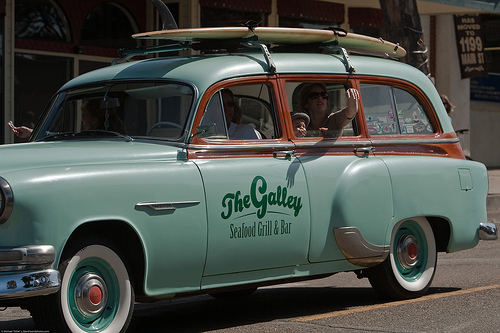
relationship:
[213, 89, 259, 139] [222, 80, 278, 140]
man looking out window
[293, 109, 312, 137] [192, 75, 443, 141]
child looking out back window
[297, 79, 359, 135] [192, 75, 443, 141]
woman looking out back window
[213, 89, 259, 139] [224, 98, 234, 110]
man wearing sunglasses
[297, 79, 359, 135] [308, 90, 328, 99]
woman wearing sunglasses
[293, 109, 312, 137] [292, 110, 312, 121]
child wearing a hat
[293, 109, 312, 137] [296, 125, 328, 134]
child has hands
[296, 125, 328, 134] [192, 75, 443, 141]
hands on back window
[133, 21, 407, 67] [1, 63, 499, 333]
surfboard on top of car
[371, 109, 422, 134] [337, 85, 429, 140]
stickers on back window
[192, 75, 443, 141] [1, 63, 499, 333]
back window of car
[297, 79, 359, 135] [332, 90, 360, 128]
woman sticking out arm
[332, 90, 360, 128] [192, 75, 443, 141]
arm stuck out of back window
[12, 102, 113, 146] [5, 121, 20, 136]
person handing out something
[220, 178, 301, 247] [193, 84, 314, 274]
writing on door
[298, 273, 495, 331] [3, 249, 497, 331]
line painted on road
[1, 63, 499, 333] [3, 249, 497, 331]
car driving down road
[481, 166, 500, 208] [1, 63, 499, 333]
sidewalk behind car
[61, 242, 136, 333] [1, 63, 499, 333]
tire of car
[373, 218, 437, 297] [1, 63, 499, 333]
back tire of car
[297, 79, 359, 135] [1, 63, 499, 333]
woman riding in car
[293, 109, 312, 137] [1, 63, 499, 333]
child riding in car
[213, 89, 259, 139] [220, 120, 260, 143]
man wearing white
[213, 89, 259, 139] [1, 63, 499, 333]
man in car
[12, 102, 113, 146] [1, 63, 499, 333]
person riding in car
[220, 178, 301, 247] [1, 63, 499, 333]
writing on car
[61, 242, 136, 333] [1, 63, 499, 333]
tire on car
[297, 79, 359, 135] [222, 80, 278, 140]
woman looking out window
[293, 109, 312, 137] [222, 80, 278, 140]
child looking out window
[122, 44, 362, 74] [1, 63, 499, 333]
surfboard racks on top of car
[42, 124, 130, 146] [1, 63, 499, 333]
windshield wipers on car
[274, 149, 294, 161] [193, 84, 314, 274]
door handle on door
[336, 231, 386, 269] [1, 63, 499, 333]
fender on car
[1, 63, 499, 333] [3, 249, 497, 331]
car on road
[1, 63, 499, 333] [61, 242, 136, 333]
car has a tire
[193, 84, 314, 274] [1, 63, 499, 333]
door of car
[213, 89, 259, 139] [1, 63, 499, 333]
man driving car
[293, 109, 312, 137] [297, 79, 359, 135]
child with woman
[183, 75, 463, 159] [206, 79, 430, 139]
trim on windows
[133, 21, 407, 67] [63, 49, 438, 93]
surfboard on roof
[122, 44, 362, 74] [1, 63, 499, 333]
surfboard racks on car